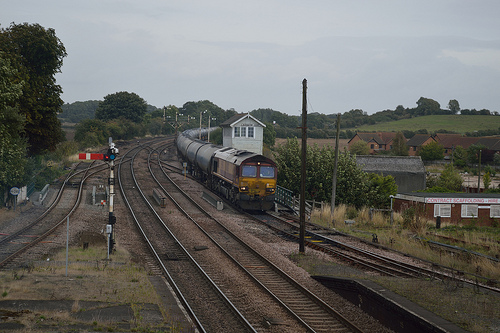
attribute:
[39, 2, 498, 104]
clouds — white 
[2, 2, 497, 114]
sky — blue 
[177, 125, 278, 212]
train — side 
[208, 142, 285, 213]
train — yellow front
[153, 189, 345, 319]
tracks — set , train 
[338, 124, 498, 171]
buildings — brown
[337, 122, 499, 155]
roofs — brown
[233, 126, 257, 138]
windows — three 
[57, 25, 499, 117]
cloud — white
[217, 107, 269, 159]
building — tall gray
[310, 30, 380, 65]
clouds — white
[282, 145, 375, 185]
bush — green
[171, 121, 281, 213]
train — black 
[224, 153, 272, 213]
engine — yellow  , dirty red 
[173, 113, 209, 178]
train — freight 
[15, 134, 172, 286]
tracks — train, split up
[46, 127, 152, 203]
edge — outer